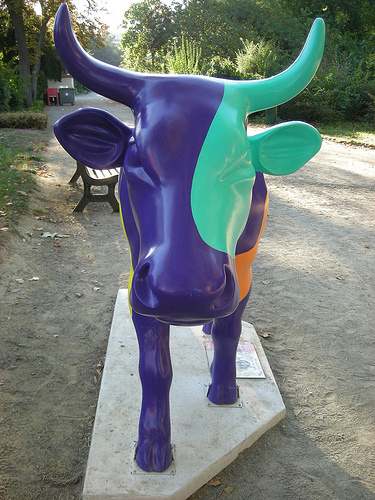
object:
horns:
[52, 1, 326, 115]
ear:
[52, 106, 129, 171]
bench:
[69, 161, 120, 214]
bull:
[52, 1, 325, 472]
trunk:
[9, 10, 34, 109]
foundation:
[81, 287, 287, 499]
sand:
[2, 102, 374, 500]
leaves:
[1, 169, 71, 253]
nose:
[128, 261, 238, 321]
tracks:
[268, 229, 373, 304]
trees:
[120, 1, 374, 119]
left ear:
[250, 118, 322, 176]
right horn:
[53, 2, 132, 110]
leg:
[130, 311, 174, 435]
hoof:
[208, 381, 242, 404]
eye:
[125, 144, 160, 190]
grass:
[0, 142, 45, 251]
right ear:
[52, 107, 127, 172]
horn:
[244, 16, 328, 118]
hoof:
[133, 439, 173, 471]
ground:
[3, 92, 374, 496]